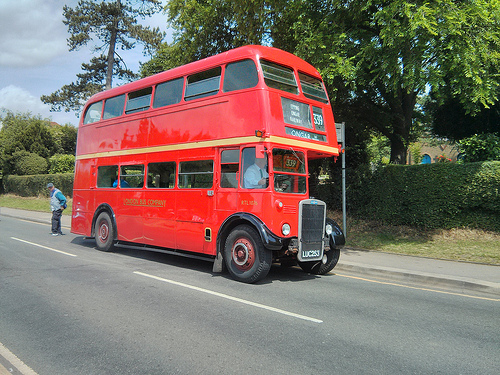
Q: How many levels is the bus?
A: Two.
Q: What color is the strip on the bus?
A: Brown.